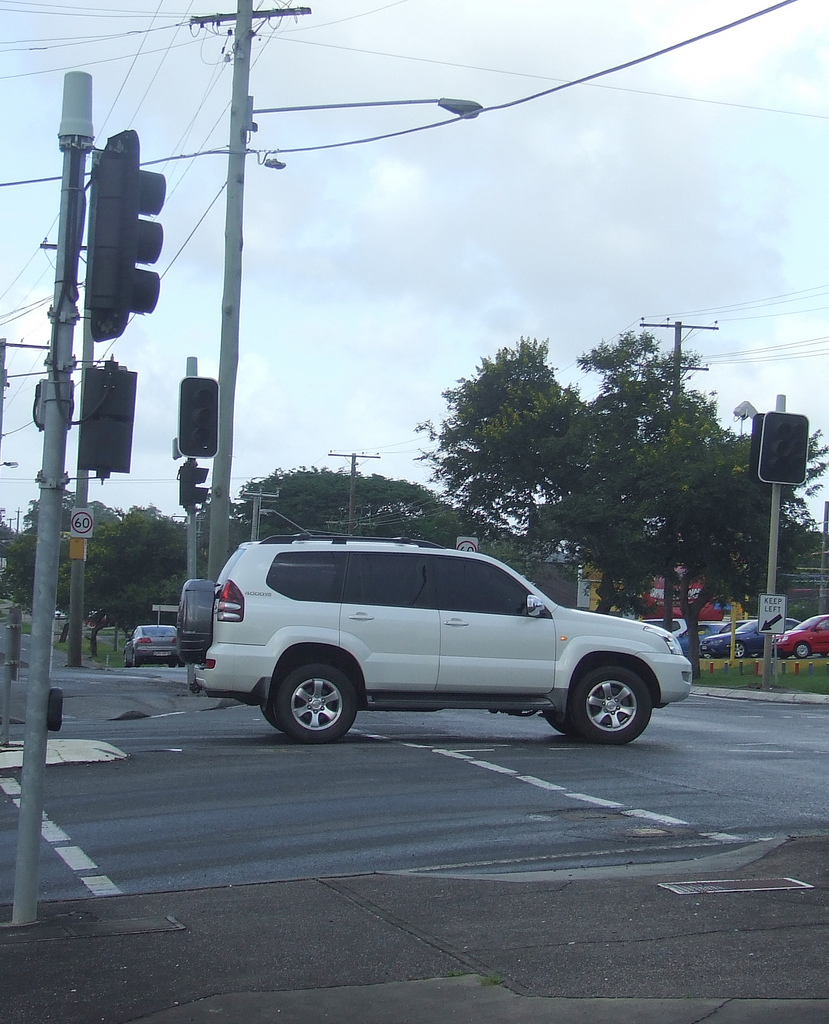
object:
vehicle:
[175, 532, 693, 743]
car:
[704, 618, 798, 661]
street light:
[8, 71, 164, 919]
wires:
[0, 0, 799, 188]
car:
[176, 536, 693, 747]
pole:
[13, 72, 95, 927]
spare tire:
[177, 580, 214, 665]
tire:
[569, 663, 653, 743]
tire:
[273, 662, 358, 745]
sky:
[0, 0, 829, 517]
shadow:
[341, 733, 565, 747]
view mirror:
[527, 595, 545, 617]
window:
[267, 551, 554, 620]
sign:
[758, 592, 789, 635]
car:
[772, 614, 829, 660]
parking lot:
[633, 616, 827, 692]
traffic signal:
[750, 411, 809, 486]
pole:
[760, 395, 786, 664]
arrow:
[761, 613, 781, 630]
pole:
[760, 484, 780, 687]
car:
[122, 624, 177, 667]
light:
[251, 98, 483, 118]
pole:
[207, 0, 255, 584]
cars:
[124, 536, 764, 746]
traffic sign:
[70, 507, 96, 561]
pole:
[68, 309, 94, 667]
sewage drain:
[657, 873, 813, 898]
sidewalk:
[504, 824, 829, 1024]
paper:
[136, 747, 182, 752]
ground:
[0, 663, 829, 1024]